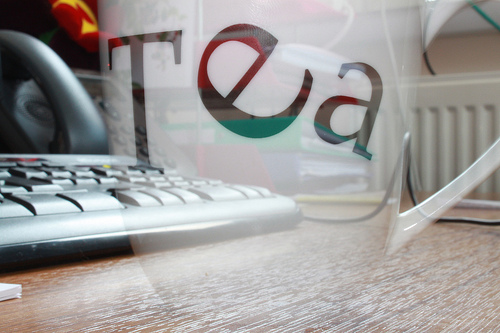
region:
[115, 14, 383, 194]
Tea written on teacup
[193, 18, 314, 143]
letter e tilted on side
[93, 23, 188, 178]
letter T capitalized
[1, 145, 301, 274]
silver keyboard behind teacup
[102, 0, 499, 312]
partially transparent white teacup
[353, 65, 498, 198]
white radiator against wall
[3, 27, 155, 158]
black phone behind keyboard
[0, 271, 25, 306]
white papers front left of keyboard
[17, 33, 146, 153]
light glare on phone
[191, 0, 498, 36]
white molding on window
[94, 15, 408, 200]
Black TEA letters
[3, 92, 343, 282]
Black and grey computer keyboard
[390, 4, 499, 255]
White handle of cup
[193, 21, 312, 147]
Black letter E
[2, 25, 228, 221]
Black corded telephone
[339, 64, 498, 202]
White AC vent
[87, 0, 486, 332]
Faded white tea cup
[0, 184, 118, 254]
Three black buttons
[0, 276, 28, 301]
White pieces of paper in the corner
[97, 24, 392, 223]
Black lettering on white faded cup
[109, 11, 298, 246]
this is a mug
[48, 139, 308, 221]
the mug is white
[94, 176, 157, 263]
this is a keyboard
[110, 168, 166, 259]
the keyboard is black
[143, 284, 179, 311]
this is a desk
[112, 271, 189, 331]
this is a wooden desk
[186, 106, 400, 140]
this says the word tea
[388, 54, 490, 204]
this is a vent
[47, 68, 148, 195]
this is a phone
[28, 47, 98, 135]
the phone is black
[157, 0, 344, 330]
this is a mug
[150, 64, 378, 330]
the mug is white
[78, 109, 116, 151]
this is a phone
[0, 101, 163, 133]
the phone is black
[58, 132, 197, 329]
this is a keyboard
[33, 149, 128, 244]
the keyboard is plastic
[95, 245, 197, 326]
this is a desk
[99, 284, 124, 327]
the desk is wooden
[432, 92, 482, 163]
this is a vent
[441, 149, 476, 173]
the vent is white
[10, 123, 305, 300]
a key board on table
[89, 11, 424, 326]
a ghost image of a mug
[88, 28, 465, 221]
tea is on the mug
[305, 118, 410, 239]
a wire shows through the image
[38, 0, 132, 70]
an orange and yellow object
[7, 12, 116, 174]
a phone in it's craddle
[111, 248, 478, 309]
a wood grain shows through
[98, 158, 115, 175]
a yellow dot on key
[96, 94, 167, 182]
a dial pad for phone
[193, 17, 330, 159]
the letter e is tilted